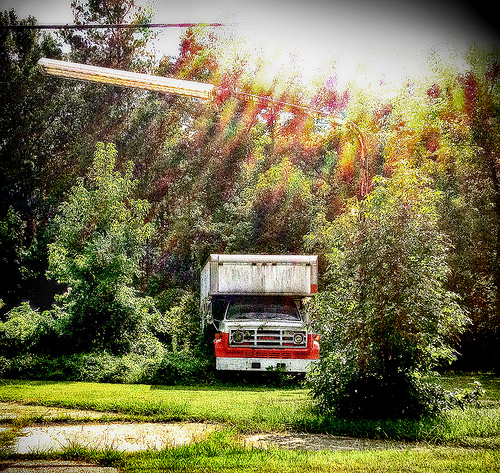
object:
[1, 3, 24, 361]
forest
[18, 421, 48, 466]
dirt land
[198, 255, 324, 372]
car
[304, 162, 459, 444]
tree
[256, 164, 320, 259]
tree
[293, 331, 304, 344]
headlight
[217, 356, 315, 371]
bumper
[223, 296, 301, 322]
windshield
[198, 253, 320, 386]
truck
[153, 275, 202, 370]
tree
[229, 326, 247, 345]
head light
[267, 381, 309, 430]
grass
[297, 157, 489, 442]
plant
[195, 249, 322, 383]
truck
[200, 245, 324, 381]
truck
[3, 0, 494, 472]
park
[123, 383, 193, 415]
grass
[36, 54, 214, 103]
light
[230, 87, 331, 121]
pole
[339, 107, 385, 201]
pole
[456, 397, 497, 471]
field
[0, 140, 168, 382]
tree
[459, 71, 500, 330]
tree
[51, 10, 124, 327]
forest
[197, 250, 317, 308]
cargo space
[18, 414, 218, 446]
big gap